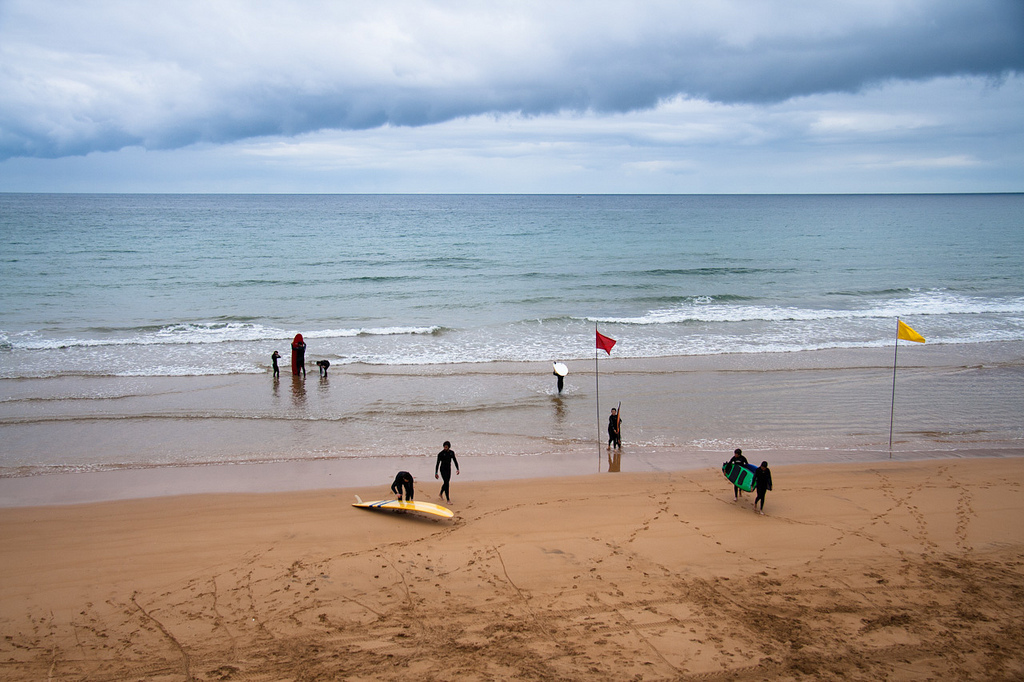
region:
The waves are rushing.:
[593, 300, 824, 329]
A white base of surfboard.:
[552, 361, 571, 375]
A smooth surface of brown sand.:
[19, 506, 171, 576]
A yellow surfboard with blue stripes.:
[350, 491, 452, 518]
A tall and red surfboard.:
[288, 331, 304, 374]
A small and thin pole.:
[891, 314, 901, 385]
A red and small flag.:
[593, 331, 619, 355]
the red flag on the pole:
[590, 322, 613, 447]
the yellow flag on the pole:
[885, 313, 923, 449]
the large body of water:
[2, 192, 1021, 478]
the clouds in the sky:
[0, 2, 1021, 198]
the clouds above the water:
[1, 0, 1022, 481]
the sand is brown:
[1, 456, 1022, 679]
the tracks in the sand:
[1, 454, 1022, 679]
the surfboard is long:
[351, 490, 454, 520]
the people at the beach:
[2, 192, 1021, 680]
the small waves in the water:
[2, 193, 1021, 473]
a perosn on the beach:
[440, 446, 483, 494]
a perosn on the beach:
[754, 448, 781, 524]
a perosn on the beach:
[580, 398, 639, 494]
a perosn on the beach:
[535, 347, 574, 420]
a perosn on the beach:
[292, 329, 316, 383]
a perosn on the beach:
[266, 339, 289, 394]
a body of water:
[394, 336, 642, 438]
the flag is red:
[589, 323, 610, 461]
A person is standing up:
[752, 453, 779, 514]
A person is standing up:
[732, 447, 751, 502]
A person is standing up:
[609, 400, 630, 446]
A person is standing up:
[391, 471, 430, 497]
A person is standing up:
[556, 354, 573, 394]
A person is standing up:
[293, 330, 310, 388]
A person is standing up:
[271, 345, 285, 369]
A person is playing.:
[556, 354, 577, 394]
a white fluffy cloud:
[457, 57, 557, 109]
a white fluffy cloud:
[571, 46, 658, 110]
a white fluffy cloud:
[343, 76, 443, 159]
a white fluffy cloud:
[413, 11, 494, 141]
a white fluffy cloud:
[287, 44, 414, 207]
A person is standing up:
[606, 397, 632, 456]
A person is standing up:
[442, 434, 469, 510]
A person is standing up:
[754, 462, 777, 513]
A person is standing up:
[730, 441, 756, 500]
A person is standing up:
[288, 333, 314, 387]